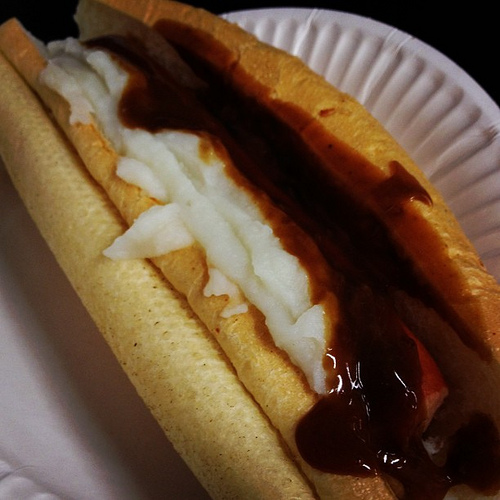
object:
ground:
[399, 134, 440, 169]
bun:
[0, 0, 500, 500]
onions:
[41, 36, 326, 395]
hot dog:
[403, 324, 449, 434]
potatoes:
[198, 117, 364, 293]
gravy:
[323, 161, 422, 390]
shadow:
[0, 169, 209, 498]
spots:
[0, 61, 314, 499]